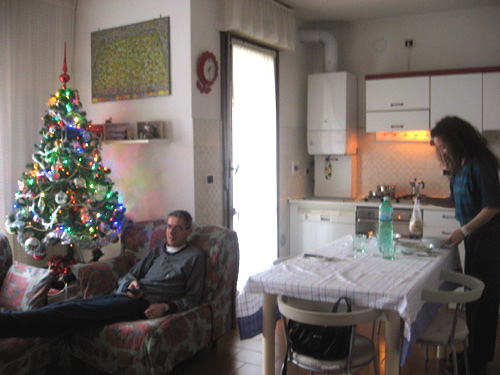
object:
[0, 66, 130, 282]
tree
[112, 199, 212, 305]
man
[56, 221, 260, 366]
chair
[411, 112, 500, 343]
woman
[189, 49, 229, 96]
clock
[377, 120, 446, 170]
light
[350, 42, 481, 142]
cabinet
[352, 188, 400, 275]
water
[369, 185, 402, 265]
bottle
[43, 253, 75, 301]
bag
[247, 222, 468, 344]
table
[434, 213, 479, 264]
hand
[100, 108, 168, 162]
shelf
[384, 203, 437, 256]
cup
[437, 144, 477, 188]
hair